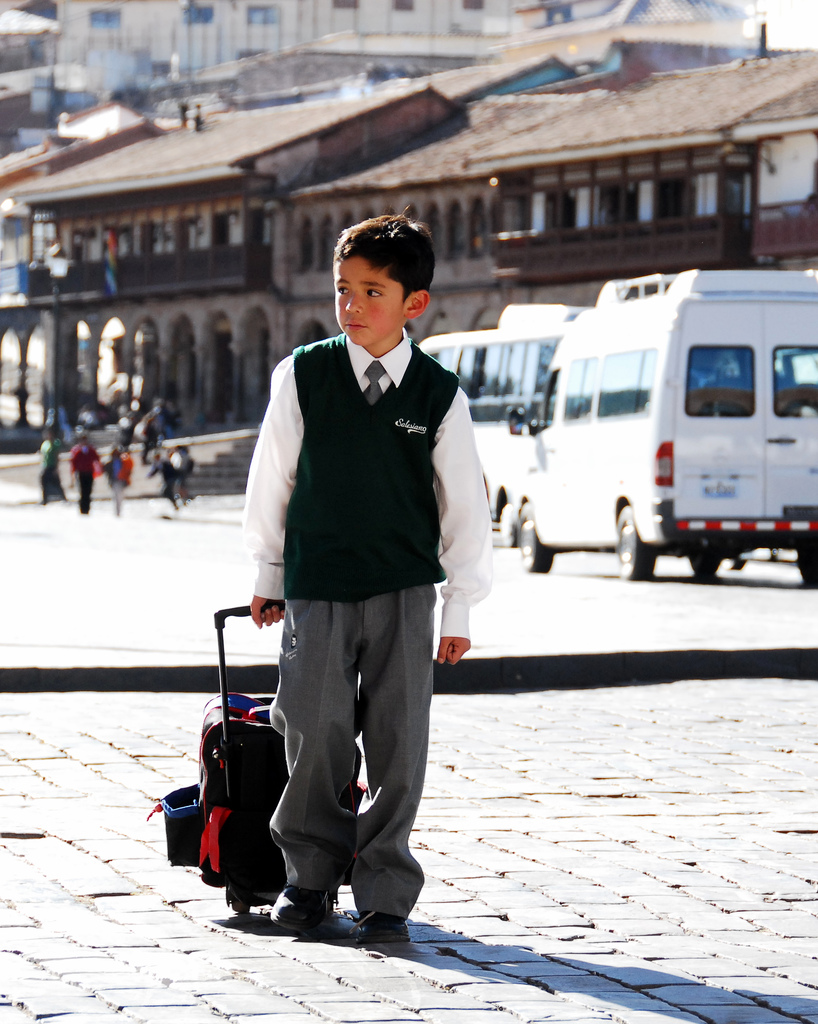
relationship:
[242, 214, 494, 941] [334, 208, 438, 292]
boy has hair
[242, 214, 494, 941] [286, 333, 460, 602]
boy has vest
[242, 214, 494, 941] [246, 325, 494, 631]
boy has shirt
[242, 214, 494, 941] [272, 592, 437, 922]
boy has slacks